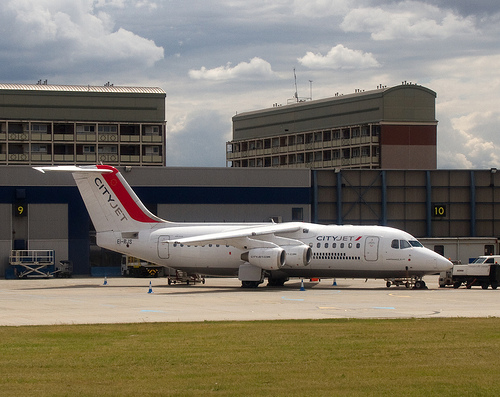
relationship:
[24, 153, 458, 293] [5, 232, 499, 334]
jet parked at terminal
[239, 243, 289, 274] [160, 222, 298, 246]
engine mounted to wing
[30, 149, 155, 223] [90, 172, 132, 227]
tail has a logo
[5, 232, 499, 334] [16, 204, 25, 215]
terminal marked with gate 9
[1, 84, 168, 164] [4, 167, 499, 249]
building behind terminal building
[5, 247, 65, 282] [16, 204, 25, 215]
lift in front gate 9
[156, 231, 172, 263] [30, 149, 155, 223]
door on tail section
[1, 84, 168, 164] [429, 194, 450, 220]
building has number 10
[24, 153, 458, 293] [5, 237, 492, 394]
jet at an airport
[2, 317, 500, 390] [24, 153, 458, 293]
grass along taxiway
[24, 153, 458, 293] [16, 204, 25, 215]
building has number gate 9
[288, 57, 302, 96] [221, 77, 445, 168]
antenna on airport building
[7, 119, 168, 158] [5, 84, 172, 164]
windows in building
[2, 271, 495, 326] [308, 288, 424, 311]
concrete has markings yellow and blue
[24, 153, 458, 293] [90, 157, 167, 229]
plane has red stripe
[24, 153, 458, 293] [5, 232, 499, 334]
jet aircraft on runway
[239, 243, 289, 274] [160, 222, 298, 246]
engines attached to wing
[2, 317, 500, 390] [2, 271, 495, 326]
grass growing next runway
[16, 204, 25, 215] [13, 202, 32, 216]
gate 9 indicating gate 9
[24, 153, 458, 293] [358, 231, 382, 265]
aircraft has front door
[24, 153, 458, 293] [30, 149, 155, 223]
plane has a tail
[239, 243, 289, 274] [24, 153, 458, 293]
engine of a plane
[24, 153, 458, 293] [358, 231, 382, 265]
plane has door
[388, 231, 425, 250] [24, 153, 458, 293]
windshield of a plane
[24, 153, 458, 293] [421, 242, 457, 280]
plane has nose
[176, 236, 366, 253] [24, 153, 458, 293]
window of plane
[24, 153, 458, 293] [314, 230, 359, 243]
plane has writing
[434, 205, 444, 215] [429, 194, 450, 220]
number 10 has number 10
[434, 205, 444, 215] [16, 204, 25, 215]
number 10 yellow gate 9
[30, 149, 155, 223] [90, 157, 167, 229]
tail has a red stripe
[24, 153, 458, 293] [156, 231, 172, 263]
airplane has exit door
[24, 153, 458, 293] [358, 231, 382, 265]
airplane has front door